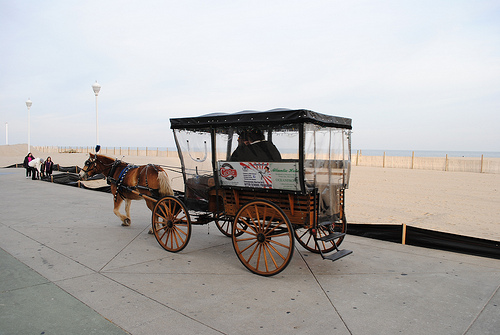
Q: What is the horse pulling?
A: A carriage with people.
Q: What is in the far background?
A: Ocean.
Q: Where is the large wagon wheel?
A: On the back of the carriage.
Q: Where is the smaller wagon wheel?
A: On the front of the carriage.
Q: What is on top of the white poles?
A: Street lights.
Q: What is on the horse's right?
A: Sandy beach.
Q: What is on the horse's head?
A: A decorative plume.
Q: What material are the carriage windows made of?
A: Clear plastic.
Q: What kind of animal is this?
A: Horse.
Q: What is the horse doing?
A: Pulling carriage.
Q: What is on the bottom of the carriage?
A: Wheels.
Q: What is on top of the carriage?
A: Roof.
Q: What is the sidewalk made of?
A: Cement.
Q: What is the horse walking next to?
A: Sand.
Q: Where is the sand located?
A: Beach.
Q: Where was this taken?
A: By the beach.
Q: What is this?
A: Horse and buggy.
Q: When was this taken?
A: During the day.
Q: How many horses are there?
A: One.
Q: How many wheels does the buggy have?
A: Four.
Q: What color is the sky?
A: Light blue.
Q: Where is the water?
A: Right of the horse.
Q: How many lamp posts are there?
A: Two.